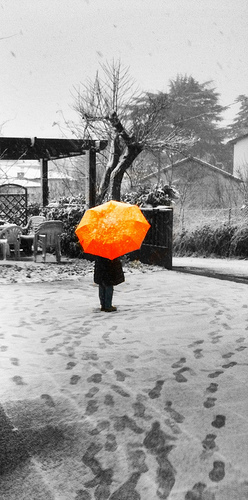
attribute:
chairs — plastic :
[1, 213, 69, 265]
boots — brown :
[98, 295, 117, 314]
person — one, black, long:
[90, 231, 124, 315]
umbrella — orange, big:
[74, 197, 146, 258]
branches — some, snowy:
[81, 64, 163, 145]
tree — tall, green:
[136, 66, 227, 146]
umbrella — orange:
[71, 194, 154, 267]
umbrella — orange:
[72, 196, 153, 261]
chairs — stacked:
[27, 214, 66, 265]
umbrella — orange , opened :
[76, 203, 139, 253]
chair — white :
[21, 213, 39, 243]